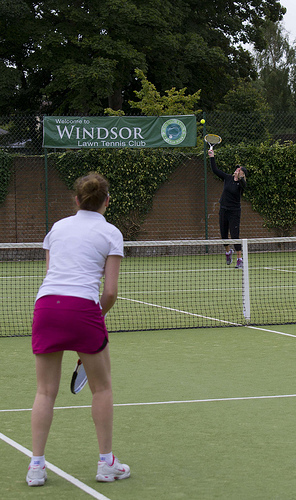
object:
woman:
[24, 172, 130, 487]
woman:
[206, 146, 246, 267]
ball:
[201, 119, 205, 124]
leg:
[78, 344, 113, 465]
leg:
[29, 334, 63, 460]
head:
[204, 134, 222, 147]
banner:
[42, 115, 196, 148]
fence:
[0, 139, 296, 255]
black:
[210, 157, 246, 253]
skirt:
[31, 294, 108, 355]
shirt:
[34, 209, 123, 310]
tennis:
[0, 109, 296, 500]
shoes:
[27, 465, 45, 485]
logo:
[115, 467, 125, 472]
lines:
[0, 436, 107, 500]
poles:
[44, 112, 47, 238]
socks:
[31, 456, 45, 469]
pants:
[218, 207, 242, 252]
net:
[0, 236, 296, 338]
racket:
[70, 359, 88, 395]